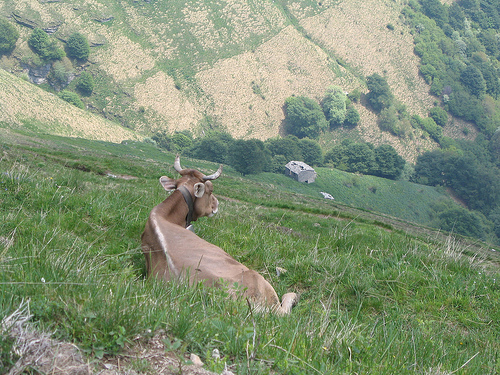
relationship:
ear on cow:
[192, 181, 205, 198] [142, 137, 321, 372]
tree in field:
[362, 71, 389, 113] [254, 16, 436, 168]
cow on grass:
[140, 149, 299, 320] [0, 68, 496, 373]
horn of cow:
[202, 164, 224, 180] [140, 149, 299, 320]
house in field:
[260, 145, 355, 202] [27, 62, 448, 368]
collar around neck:
[169, 177, 199, 221] [160, 187, 198, 230]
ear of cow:
[192, 181, 205, 198] [124, 152, 300, 322]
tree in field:
[319, 80, 351, 124] [114, 65, 492, 228]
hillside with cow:
[11, 5, 495, 373] [140, 149, 299, 320]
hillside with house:
[11, 5, 495, 373] [282, 158, 316, 184]